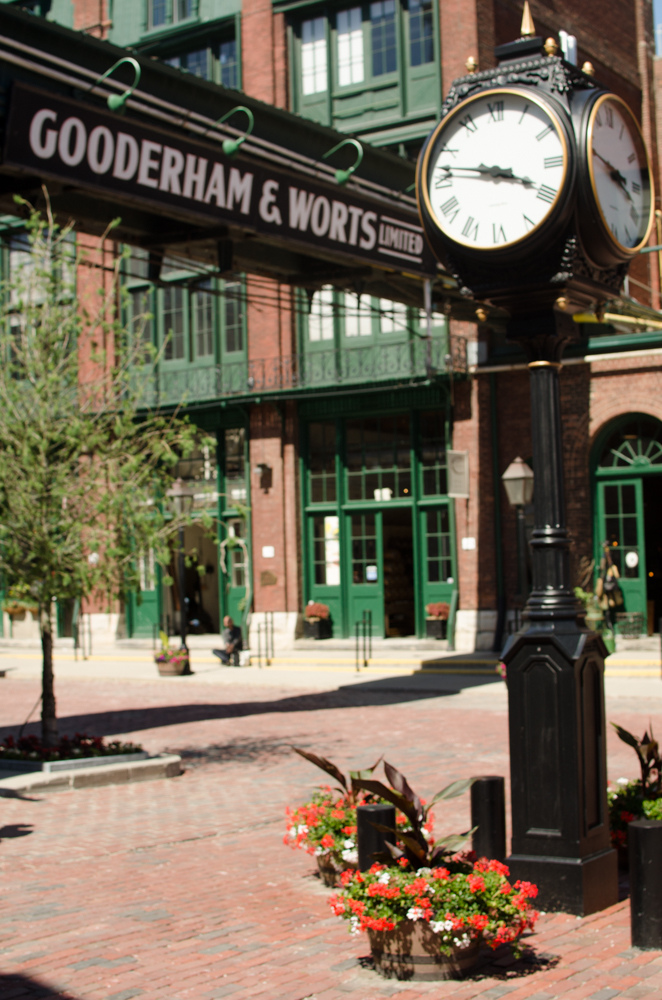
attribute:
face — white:
[415, 83, 571, 256]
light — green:
[97, 89, 147, 127]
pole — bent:
[99, 54, 147, 85]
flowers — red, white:
[322, 846, 548, 950]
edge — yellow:
[78, 662, 458, 666]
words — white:
[25, 105, 423, 261]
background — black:
[12, 39, 415, 271]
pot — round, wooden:
[360, 918, 498, 984]